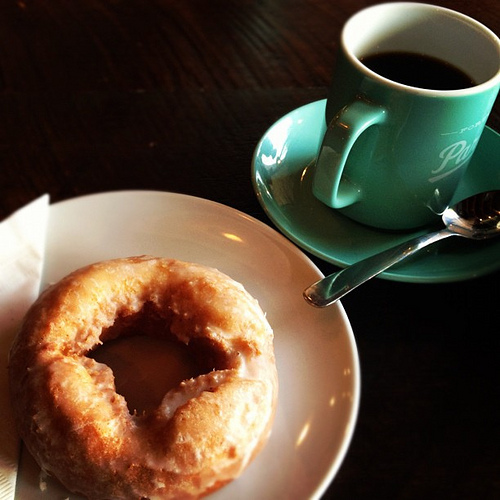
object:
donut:
[5, 251, 281, 500]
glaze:
[208, 270, 279, 470]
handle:
[301, 227, 457, 309]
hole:
[67, 293, 236, 426]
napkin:
[0, 195, 48, 498]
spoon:
[297, 194, 500, 310]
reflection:
[287, 365, 356, 448]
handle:
[310, 98, 387, 211]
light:
[295, 416, 314, 449]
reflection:
[255, 115, 296, 205]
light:
[222, 233, 243, 243]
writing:
[431, 140, 467, 174]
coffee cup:
[310, 0, 500, 234]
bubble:
[236, 352, 240, 356]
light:
[260, 113, 291, 165]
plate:
[0, 188, 366, 499]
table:
[9, 0, 500, 500]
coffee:
[354, 47, 479, 91]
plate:
[243, 82, 500, 282]